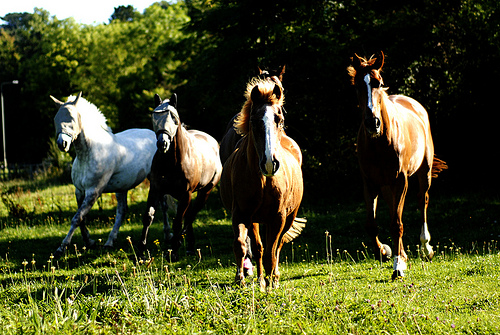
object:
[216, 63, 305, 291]
horse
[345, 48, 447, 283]
horse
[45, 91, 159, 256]
horse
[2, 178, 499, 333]
grass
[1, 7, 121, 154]
trees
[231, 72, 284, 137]
mane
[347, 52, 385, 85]
mane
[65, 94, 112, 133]
mane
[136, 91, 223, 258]
horse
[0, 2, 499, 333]
field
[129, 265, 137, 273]
flowers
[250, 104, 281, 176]
face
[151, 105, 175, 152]
face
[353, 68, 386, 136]
face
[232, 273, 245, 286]
hooves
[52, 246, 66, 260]
hooves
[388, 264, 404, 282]
hooves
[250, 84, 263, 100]
ears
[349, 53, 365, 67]
ears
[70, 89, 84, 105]
ears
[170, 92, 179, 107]
ears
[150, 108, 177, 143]
mask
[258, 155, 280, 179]
nose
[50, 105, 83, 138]
mask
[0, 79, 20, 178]
streetlight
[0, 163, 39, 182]
fence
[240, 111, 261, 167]
neck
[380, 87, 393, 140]
neck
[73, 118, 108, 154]
neck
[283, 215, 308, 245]
tail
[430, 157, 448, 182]
tail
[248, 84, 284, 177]
head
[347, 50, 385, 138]
head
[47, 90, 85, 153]
head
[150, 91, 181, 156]
head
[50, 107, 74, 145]
face